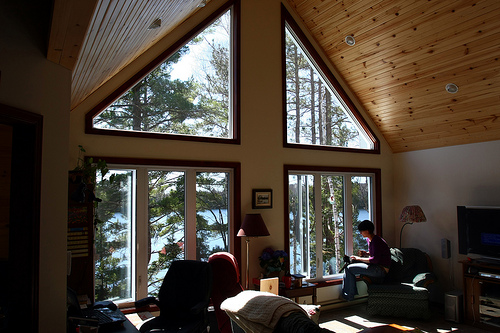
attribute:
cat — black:
[337, 255, 364, 271]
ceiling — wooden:
[329, 19, 465, 152]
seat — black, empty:
[126, 257, 220, 330]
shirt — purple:
[363, 238, 392, 268]